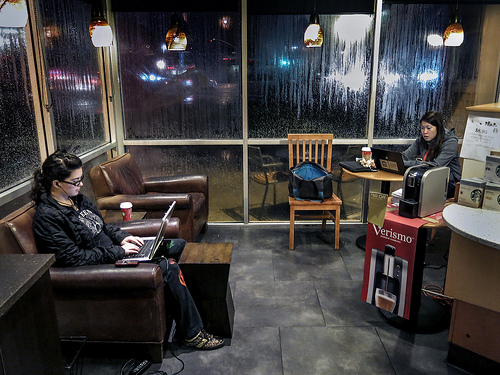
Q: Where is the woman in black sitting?
A: Leather chair.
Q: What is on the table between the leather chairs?
A: Cup.